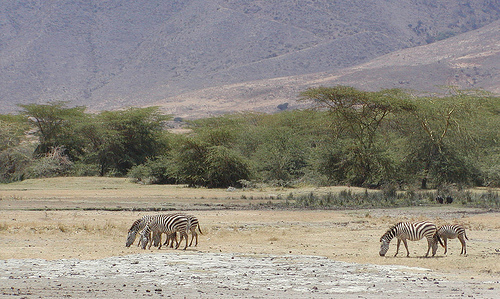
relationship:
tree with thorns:
[93, 104, 174, 177] [105, 115, 159, 148]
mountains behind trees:
[0, 0, 500, 116] [42, 69, 414, 168]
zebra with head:
[432, 224, 469, 256] [123, 222, 140, 249]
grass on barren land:
[272, 207, 313, 250] [0, 175, 499, 299]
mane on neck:
[381, 228, 391, 236] [386, 232, 398, 239]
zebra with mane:
[378, 221, 444, 259] [381, 228, 391, 236]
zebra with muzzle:
[378, 221, 444, 259] [376, 245, 388, 257]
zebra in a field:
[119, 213, 194, 245] [10, 206, 474, 290]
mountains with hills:
[4, 2, 493, 116] [6, 7, 23, 11]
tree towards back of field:
[293, 83, 418, 187] [5, 170, 482, 291]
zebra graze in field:
[125, 214, 179, 248] [9, 181, 498, 292]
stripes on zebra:
[415, 221, 430, 236] [378, 222, 438, 257]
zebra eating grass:
[378, 221, 444, 259] [0, 173, 498, 274]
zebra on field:
[125, 214, 179, 248] [5, 170, 482, 291]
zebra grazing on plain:
[125, 214, 179, 248] [0, 148, 497, 298]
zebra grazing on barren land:
[138, 211, 188, 251] [5, 167, 499, 297]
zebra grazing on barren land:
[124, 208, 205, 247] [5, 167, 499, 297]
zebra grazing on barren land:
[376, 217, 439, 263] [5, 167, 499, 297]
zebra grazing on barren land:
[429, 220, 471, 257] [5, 167, 499, 297]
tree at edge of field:
[337, 74, 408, 163] [9, 181, 498, 292]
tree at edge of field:
[394, 128, 485, 190] [9, 181, 498, 292]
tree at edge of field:
[40, 85, 110, 150] [9, 181, 498, 292]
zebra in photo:
[378, 221, 444, 259] [3, 1, 484, 296]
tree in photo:
[167, 136, 257, 185] [3, 1, 484, 296]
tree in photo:
[394, 103, 484, 193] [3, 1, 484, 296]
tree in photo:
[79, 95, 167, 175] [3, 1, 484, 296]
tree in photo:
[293, 83, 418, 187] [3, 1, 484, 296]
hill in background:
[212, 29, 413, 83] [3, 4, 499, 114]